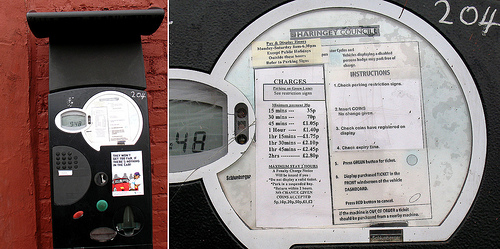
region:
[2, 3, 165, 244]
brick wall painted red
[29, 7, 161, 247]
black machine against wall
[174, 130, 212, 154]
two black digital numbers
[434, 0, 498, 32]
handwritten white numbers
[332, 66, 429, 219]
instructions written in black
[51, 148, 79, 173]
rows of black buttons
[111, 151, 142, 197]
sticker with cartoon on bottom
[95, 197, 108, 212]
round green button on black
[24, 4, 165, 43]
flat lid on machine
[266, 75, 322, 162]
list of charges in black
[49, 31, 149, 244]
pre-paid town parking meter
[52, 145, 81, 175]
key pad on meter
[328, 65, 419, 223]
instructions on how to use parking meter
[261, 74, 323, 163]
prices charged for time car will be parked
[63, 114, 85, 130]
countdown timer on meter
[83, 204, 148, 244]
money slots on meter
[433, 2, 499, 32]
hand written meter number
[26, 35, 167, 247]
brick wall behind meter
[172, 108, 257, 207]
crack in meter face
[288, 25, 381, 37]
name of town council that voted to install meter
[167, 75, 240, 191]
An led screen.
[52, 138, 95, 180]
a control panel on a device.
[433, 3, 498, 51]
the number 204 written down.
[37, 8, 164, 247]
a parking meter near a wall.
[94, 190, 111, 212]
a green button on a parking meter.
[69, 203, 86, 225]
a red button on a parking meter.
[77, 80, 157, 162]
a sticker on a parking meter.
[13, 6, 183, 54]
the top of a parking meter.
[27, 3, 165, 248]
A black parking meter.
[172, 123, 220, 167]
the number 48 on a lcd screen.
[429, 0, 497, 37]
a number in upper right corner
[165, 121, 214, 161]
a digital number in the middle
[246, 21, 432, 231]
writing on a paper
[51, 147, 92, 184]
small black buttons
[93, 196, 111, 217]
a green button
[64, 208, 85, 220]
a red button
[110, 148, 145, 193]
a picture of a car an a man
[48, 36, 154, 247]
a black box on bricks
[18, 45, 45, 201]
red brick wall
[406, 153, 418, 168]
a black and white circle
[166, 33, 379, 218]
this is a black scale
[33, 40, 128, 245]
this is a sound box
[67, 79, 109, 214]
this is a black box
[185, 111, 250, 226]
this is a digital number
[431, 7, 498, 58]
this is a number 204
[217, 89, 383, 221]
this is a number of writings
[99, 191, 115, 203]
this is a green button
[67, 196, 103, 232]
this is a red button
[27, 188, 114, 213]
the button is rubber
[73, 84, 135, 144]
this is a round circle